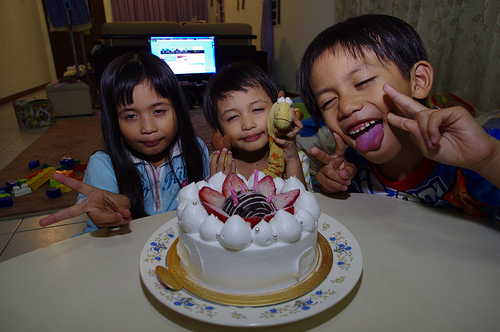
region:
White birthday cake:
[146, 146, 360, 316]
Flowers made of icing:
[161, 156, 318, 239]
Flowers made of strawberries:
[196, 172, 302, 223]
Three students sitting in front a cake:
[39, 46, 428, 223]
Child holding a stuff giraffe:
[195, 46, 310, 203]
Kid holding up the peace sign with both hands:
[298, 99, 488, 201]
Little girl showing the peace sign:
[48, 63, 170, 223]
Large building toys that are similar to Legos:
[1, 139, 121, 224]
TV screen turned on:
[92, 10, 240, 76]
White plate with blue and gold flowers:
[328, 213, 378, 300]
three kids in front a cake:
[35, 13, 499, 329]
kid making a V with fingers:
[285, 4, 499, 233]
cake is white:
[168, 159, 337, 308]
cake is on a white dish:
[125, 160, 377, 329]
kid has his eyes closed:
[201, 62, 303, 174]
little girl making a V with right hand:
[33, 34, 218, 251]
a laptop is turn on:
[136, 22, 225, 81]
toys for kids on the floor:
[5, 142, 80, 212]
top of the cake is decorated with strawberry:
[183, 159, 306, 236]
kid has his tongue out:
[289, 6, 464, 193]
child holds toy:
[259, 76, 314, 176]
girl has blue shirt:
[80, 128, 230, 193]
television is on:
[130, 33, 231, 88]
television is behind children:
[139, 26, 216, 81]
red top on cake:
[201, 141, 309, 264]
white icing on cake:
[170, 155, 326, 255]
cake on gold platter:
[155, 200, 337, 300]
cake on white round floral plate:
[131, 211, 353, 327]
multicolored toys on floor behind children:
[7, 151, 89, 218]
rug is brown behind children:
[15, 91, 105, 204]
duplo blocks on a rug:
[0, 146, 100, 213]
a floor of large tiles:
[0, 205, 85, 257]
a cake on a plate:
[170, 170, 335, 297]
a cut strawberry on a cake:
[270, 180, 300, 206]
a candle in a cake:
[250, 157, 260, 192]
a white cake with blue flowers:
[132, 205, 363, 317]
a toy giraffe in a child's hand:
[260, 85, 300, 180]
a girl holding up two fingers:
[76, 55, 222, 240]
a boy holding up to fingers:
[305, 15, 491, 206]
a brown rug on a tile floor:
[0, 112, 218, 214]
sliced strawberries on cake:
[205, 171, 290, 235]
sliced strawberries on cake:
[199, 192, 301, 248]